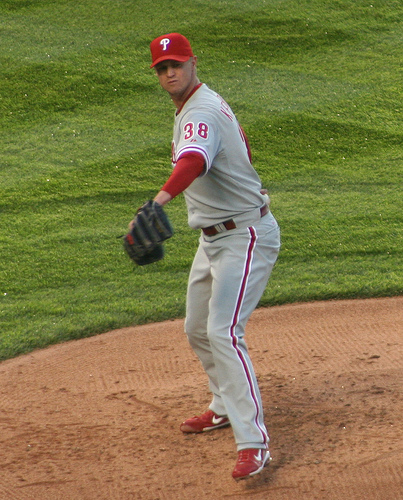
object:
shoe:
[226, 447, 282, 483]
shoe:
[176, 408, 233, 436]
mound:
[7, 299, 402, 498]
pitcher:
[117, 31, 288, 482]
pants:
[180, 228, 285, 448]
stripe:
[229, 226, 271, 452]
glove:
[124, 202, 175, 266]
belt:
[200, 208, 274, 239]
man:
[122, 21, 286, 482]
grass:
[3, 2, 402, 291]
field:
[6, 4, 402, 499]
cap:
[145, 32, 193, 66]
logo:
[159, 35, 173, 55]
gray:
[244, 165, 248, 171]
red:
[187, 163, 189, 166]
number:
[182, 118, 209, 142]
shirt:
[159, 152, 207, 205]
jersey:
[171, 90, 267, 223]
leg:
[208, 234, 284, 482]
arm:
[145, 128, 207, 224]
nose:
[166, 68, 176, 77]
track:
[248, 334, 385, 368]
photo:
[2, 1, 400, 499]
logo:
[254, 449, 266, 462]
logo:
[210, 414, 226, 426]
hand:
[128, 209, 158, 232]